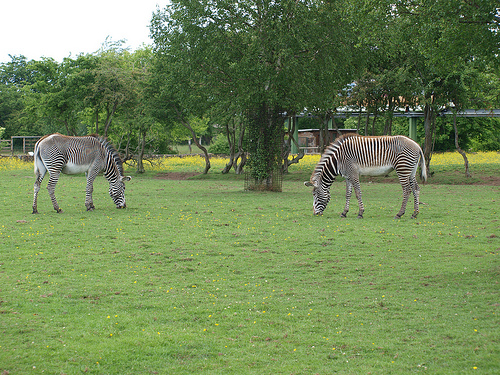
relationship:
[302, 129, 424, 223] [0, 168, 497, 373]
zebra standing in field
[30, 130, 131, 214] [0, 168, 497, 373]
zebra standing in field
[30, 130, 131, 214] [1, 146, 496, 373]
zebra grazing grass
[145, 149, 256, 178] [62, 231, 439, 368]
yellow flowers in grass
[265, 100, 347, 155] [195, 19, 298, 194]
house behind trees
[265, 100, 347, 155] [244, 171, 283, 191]
house behind foilage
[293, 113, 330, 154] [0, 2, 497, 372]
building in park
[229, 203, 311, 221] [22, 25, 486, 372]
wall in park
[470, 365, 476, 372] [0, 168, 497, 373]
flowers in field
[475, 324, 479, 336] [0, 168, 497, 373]
flowers in field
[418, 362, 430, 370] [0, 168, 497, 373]
flowers in field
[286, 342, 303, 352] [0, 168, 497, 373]
flowers in field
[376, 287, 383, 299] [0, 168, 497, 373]
flowers in field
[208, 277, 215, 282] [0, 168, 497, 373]
flower in field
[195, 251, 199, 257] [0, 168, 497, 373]
flower in field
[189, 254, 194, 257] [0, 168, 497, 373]
flower in field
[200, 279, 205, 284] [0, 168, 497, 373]
flower in field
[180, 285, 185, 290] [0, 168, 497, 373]
flower in field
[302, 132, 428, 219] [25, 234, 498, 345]
zebra grazing in field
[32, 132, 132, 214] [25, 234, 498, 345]
zebra grazing in field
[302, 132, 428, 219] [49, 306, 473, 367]
zebra grazing in field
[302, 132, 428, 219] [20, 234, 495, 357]
zebra eating grass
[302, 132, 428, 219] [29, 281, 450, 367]
zebra eating grass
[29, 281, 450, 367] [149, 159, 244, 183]
grass in a field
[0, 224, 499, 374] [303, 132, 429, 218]
field for zebras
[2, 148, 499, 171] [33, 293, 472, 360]
dandelions throughout field